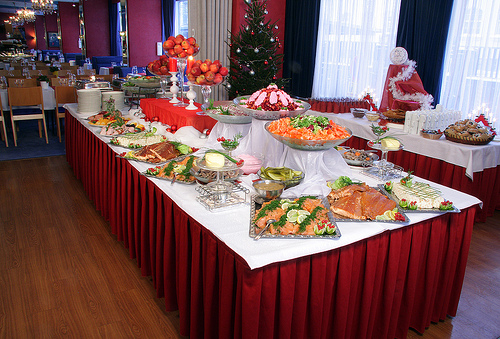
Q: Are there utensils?
A: No, there are no utensils.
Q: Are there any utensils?
A: No, there are no utensils.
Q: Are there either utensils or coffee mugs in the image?
A: No, there are no utensils or coffee mugs.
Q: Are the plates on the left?
A: Yes, the plates are on the left of the image.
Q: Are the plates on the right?
A: No, the plates are on the left of the image.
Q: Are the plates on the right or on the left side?
A: The plates are on the left of the image.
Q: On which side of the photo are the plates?
A: The plates are on the left of the image.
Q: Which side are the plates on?
A: The plates are on the left of the image.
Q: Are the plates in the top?
A: Yes, the plates are in the top of the image.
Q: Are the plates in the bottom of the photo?
A: No, the plates are in the top of the image.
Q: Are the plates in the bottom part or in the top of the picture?
A: The plates are in the top of the image.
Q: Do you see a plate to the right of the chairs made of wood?
A: Yes, there are plates to the right of the chairs.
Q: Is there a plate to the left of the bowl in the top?
A: Yes, there are plates to the left of the bowl.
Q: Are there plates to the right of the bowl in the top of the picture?
A: No, the plates are to the left of the bowl.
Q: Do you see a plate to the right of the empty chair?
A: Yes, there are plates to the right of the chair.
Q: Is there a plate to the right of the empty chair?
A: Yes, there are plates to the right of the chair.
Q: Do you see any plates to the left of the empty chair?
A: No, the plates are to the right of the chair.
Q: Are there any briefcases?
A: No, there are no briefcases.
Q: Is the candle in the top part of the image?
A: Yes, the candle is in the top of the image.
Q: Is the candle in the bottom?
A: No, the candle is in the top of the image.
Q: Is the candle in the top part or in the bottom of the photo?
A: The candle is in the top of the image.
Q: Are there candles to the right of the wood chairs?
A: Yes, there is a candle to the right of the chairs.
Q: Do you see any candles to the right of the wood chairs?
A: Yes, there is a candle to the right of the chairs.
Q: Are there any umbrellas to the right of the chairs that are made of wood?
A: No, there is a candle to the right of the chairs.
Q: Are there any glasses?
A: No, there are no glasses.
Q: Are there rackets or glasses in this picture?
A: No, there are no glasses or rackets.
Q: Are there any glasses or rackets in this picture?
A: No, there are no glasses or rackets.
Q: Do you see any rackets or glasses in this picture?
A: No, there are no glasses or rackets.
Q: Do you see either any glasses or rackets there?
A: No, there are no glasses or rackets.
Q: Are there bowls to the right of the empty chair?
A: Yes, there is a bowl to the right of the chair.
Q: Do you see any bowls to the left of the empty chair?
A: No, the bowl is to the right of the chair.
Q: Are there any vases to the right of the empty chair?
A: No, there is a bowl to the right of the chair.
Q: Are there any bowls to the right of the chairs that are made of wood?
A: Yes, there is a bowl to the right of the chairs.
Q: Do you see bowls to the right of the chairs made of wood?
A: Yes, there is a bowl to the right of the chairs.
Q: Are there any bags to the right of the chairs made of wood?
A: No, there is a bowl to the right of the chairs.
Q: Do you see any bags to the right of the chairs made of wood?
A: No, there is a bowl to the right of the chairs.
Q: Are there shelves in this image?
A: No, there are no shelves.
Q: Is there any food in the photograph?
A: Yes, there is food.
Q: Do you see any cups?
A: No, there are no cups.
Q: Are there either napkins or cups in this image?
A: No, there are no cups or napkins.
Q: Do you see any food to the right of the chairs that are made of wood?
A: Yes, there is food to the right of the chairs.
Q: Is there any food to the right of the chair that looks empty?
A: Yes, there is food to the right of the chair.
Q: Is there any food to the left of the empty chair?
A: No, the food is to the right of the chair.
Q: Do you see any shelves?
A: No, there are no shelves.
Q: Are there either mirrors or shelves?
A: No, there are no shelves or mirrors.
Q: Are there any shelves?
A: No, there are no shelves.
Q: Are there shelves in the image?
A: No, there are no shelves.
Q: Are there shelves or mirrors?
A: No, there are no shelves or mirrors.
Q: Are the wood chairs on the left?
A: Yes, the chairs are on the left of the image.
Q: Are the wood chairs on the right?
A: No, the chairs are on the left of the image.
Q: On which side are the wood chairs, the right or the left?
A: The chairs are on the left of the image.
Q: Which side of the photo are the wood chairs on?
A: The chairs are on the left of the image.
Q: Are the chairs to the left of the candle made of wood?
A: Yes, the chairs are made of wood.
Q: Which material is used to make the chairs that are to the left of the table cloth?
A: The chairs are made of wood.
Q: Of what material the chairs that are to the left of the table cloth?
A: The chairs are made of wood.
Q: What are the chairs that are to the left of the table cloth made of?
A: The chairs are made of wood.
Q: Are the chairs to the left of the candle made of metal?
A: No, the chairs are made of wood.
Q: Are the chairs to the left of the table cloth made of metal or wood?
A: The chairs are made of wood.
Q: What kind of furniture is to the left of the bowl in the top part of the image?
A: The pieces of furniture are chairs.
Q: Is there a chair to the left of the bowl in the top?
A: Yes, there are chairs to the left of the bowl.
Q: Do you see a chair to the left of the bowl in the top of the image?
A: Yes, there are chairs to the left of the bowl.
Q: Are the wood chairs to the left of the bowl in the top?
A: Yes, the chairs are to the left of the bowl.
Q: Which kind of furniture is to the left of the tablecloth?
A: The pieces of furniture are chairs.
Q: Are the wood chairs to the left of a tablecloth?
A: Yes, the chairs are to the left of a tablecloth.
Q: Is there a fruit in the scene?
A: Yes, there is a fruit.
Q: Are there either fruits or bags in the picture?
A: Yes, there is a fruit.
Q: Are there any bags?
A: No, there are no bags.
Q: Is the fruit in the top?
A: Yes, the fruit is in the top of the image.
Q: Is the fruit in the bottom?
A: No, the fruit is in the top of the image.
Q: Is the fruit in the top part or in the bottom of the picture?
A: The fruit is in the top of the image.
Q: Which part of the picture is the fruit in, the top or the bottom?
A: The fruit is in the top of the image.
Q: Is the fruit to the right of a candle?
A: Yes, the fruit is to the right of a candle.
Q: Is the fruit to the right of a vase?
A: No, the fruit is to the right of a candle.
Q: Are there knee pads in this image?
A: No, there are no knee pads.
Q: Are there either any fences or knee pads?
A: No, there are no knee pads or fences.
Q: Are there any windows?
A: Yes, there is a window.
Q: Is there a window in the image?
A: Yes, there is a window.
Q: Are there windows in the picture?
A: Yes, there is a window.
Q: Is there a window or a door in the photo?
A: Yes, there is a window.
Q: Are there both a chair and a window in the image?
A: Yes, there are both a window and a chair.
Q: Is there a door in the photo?
A: No, there are no doors.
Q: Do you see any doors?
A: No, there are no doors.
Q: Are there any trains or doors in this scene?
A: No, there are no doors or trains.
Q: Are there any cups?
A: No, there are no cups.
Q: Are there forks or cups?
A: No, there are no cups or forks.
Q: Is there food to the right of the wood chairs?
A: Yes, there is food to the right of the chairs.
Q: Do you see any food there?
A: Yes, there is food.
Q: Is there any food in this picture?
A: Yes, there is food.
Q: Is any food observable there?
A: Yes, there is food.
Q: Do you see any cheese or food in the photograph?
A: Yes, there is food.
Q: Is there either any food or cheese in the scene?
A: Yes, there is food.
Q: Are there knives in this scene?
A: No, there are no knives.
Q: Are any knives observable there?
A: No, there are no knives.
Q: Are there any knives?
A: No, there are no knives.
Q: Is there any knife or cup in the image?
A: No, there are no knives or cups.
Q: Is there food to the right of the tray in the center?
A: Yes, there is food to the right of the tray.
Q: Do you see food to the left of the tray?
A: No, the food is to the right of the tray.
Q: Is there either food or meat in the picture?
A: Yes, there is food.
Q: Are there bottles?
A: No, there are no bottles.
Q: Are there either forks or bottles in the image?
A: No, there are no bottles or forks.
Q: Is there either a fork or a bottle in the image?
A: No, there are no bottles or forks.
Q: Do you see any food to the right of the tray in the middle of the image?
A: Yes, there is food to the right of the tray.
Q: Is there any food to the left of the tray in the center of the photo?
A: No, the food is to the right of the tray.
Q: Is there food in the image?
A: Yes, there is food.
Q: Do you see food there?
A: Yes, there is food.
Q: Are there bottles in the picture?
A: No, there are no bottles.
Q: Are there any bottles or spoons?
A: No, there are no bottles or spoons.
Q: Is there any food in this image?
A: Yes, there is food.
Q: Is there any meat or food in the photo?
A: Yes, there is food.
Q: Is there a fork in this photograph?
A: No, there are no forks.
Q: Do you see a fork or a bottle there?
A: No, there are no forks or bottles.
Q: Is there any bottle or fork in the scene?
A: No, there are no forks or bottles.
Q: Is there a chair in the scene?
A: Yes, there is a chair.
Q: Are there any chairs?
A: Yes, there is a chair.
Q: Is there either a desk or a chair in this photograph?
A: Yes, there is a chair.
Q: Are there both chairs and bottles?
A: No, there is a chair but no bottles.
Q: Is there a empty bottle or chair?
A: Yes, there is an empty chair.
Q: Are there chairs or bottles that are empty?
A: Yes, the chair is empty.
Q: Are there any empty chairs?
A: Yes, there is an empty chair.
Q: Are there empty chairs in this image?
A: Yes, there is an empty chair.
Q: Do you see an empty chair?
A: Yes, there is an empty chair.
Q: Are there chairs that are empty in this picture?
A: Yes, there is an empty chair.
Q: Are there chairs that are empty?
A: Yes, there is a chair that is empty.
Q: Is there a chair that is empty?
A: Yes, there is a chair that is empty.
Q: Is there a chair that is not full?
A: Yes, there is a empty chair.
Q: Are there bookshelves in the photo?
A: No, there are no bookshelves.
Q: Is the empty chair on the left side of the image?
A: Yes, the chair is on the left of the image.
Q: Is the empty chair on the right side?
A: No, the chair is on the left of the image.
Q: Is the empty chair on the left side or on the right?
A: The chair is on the left of the image.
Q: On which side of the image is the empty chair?
A: The chair is on the left of the image.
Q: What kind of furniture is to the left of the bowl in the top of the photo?
A: The piece of furniture is a chair.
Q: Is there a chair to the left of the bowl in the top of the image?
A: Yes, there is a chair to the left of the bowl.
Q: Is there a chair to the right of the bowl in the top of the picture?
A: No, the chair is to the left of the bowl.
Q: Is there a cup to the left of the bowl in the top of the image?
A: No, there is a chair to the left of the bowl.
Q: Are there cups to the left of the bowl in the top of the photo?
A: No, there is a chair to the left of the bowl.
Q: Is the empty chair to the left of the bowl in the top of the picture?
A: Yes, the chair is to the left of the bowl.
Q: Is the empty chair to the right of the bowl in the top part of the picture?
A: No, the chair is to the left of the bowl.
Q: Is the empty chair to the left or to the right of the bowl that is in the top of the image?
A: The chair is to the left of the bowl.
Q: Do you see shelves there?
A: No, there are no shelves.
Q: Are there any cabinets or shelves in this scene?
A: No, there are no shelves or cabinets.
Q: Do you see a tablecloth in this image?
A: Yes, there is a tablecloth.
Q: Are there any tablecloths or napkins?
A: Yes, there is a tablecloth.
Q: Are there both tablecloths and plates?
A: Yes, there are both a tablecloth and a plate.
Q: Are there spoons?
A: No, there are no spoons.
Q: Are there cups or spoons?
A: No, there are no spoons or cups.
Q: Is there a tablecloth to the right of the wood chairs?
A: Yes, there is a tablecloth to the right of the chairs.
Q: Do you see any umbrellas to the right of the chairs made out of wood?
A: No, there is a tablecloth to the right of the chairs.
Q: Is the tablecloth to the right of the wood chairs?
A: Yes, the tablecloth is to the right of the chairs.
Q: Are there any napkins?
A: No, there are no napkins.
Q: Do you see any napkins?
A: No, there are no napkins.